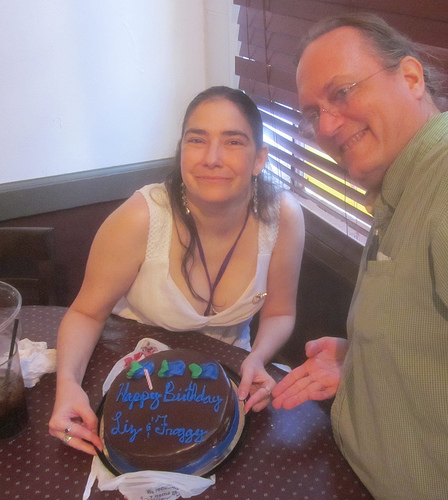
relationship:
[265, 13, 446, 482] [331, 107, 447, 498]
man has shirt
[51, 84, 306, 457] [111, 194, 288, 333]
lady wearing shirt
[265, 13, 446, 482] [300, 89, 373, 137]
man wearing glasses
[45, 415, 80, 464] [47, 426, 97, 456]
rings on woman's finger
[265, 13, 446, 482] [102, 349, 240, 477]
man happy about birthday cake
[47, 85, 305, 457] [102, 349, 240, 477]
lady happy about birthday cake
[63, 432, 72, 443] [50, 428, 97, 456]
ring on her finger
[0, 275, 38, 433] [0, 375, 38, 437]
clear glass of soda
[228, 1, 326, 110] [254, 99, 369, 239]
brown shutters on window